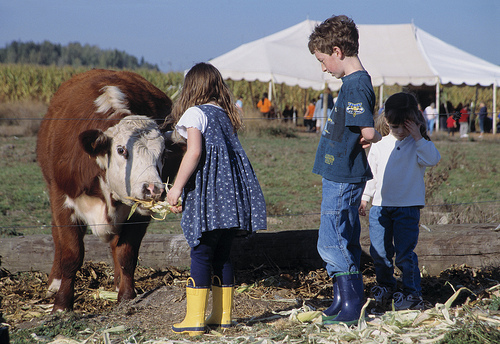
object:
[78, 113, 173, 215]
cow head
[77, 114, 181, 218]
head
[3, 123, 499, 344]
ground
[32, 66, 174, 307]
cow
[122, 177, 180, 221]
corn husks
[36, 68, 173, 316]
cow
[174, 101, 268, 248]
dress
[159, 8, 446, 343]
kids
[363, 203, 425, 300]
jeans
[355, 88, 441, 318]
kid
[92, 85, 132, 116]
spot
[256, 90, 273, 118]
person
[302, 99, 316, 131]
person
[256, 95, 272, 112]
shirt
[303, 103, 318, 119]
shirt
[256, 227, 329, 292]
shade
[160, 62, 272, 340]
girl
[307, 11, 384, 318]
boy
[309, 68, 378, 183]
t-shirt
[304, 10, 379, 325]
boy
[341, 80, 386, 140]
arm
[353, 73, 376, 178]
back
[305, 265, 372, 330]
boots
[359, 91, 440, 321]
boy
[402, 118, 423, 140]
hand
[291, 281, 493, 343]
corn husks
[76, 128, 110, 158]
ear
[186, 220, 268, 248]
edge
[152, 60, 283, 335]
girl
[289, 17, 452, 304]
two boys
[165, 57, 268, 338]
kid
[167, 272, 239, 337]
boots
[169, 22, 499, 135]
canopy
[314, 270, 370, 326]
boots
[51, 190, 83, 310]
leg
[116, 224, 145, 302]
leg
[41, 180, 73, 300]
leg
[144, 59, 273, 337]
girl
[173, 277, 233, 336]
boots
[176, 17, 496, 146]
fair area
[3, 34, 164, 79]
treeline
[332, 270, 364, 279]
edge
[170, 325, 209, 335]
edge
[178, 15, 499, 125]
tent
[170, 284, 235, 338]
boots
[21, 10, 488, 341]
farm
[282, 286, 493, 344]
pile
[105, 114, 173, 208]
face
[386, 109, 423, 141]
face